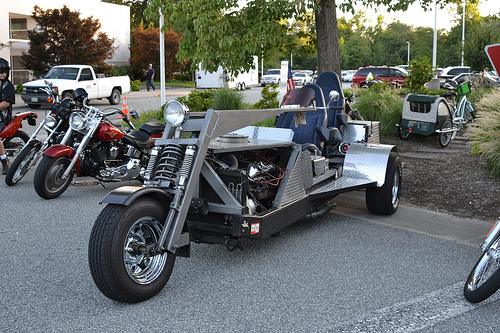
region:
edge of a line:
[415, 264, 447, 296]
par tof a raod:
[410, 270, 440, 293]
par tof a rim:
[124, 232, 169, 277]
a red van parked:
[353, 67, 410, 89]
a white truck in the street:
[26, 70, 129, 102]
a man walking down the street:
[143, 60, 153, 88]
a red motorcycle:
[48, 100, 170, 195]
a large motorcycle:
[84, 88, 404, 304]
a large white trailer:
[194, 53, 261, 88]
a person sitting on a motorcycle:
[2, 68, 32, 188]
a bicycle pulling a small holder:
[389, 81, 481, 139]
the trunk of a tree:
[312, 3, 341, 72]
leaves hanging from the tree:
[141, 1, 324, 76]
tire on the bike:
[81, 198, 171, 308]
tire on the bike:
[26, 161, 84, 203]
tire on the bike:
[361, 160, 421, 227]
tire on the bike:
[428, 124, 457, 145]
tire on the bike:
[459, 254, 499, 310]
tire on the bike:
[8, 150, 26, 190]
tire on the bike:
[6, 132, 28, 157]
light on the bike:
[160, 103, 182, 126]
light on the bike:
[63, 110, 80, 125]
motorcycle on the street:
[114, 89, 405, 309]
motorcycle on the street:
[43, 97, 153, 186]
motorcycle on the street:
[405, 76, 485, 161]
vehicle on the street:
[25, 67, 136, 109]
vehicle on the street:
[346, 58, 404, 88]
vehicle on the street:
[288, 69, 308, 86]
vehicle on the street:
[263, 63, 287, 83]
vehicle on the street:
[434, 55, 472, 81]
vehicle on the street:
[338, 64, 354, 80]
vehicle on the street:
[296, 68, 311, 78]